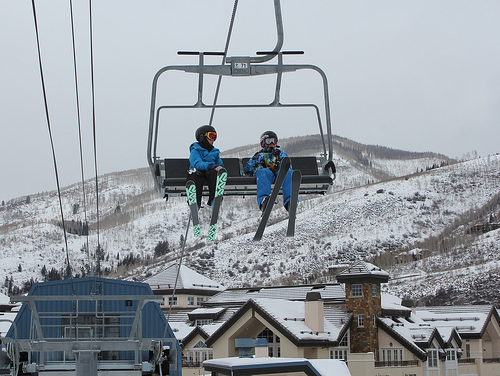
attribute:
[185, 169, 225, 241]
skis — blue, black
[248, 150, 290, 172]
jacket — blue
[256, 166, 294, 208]
pants — blue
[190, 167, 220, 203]
pants — black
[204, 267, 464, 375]
house — tan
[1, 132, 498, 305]
mountain — white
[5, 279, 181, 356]
building — blue, metal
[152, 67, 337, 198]
ski lift — metal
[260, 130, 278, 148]
helmet — black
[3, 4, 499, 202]
sky — gray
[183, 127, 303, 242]
skiers — sitting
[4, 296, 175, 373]
lift — moving, gray, blue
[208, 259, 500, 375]
ski lodge — white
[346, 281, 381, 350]
tower — brick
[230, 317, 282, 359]
arch — white